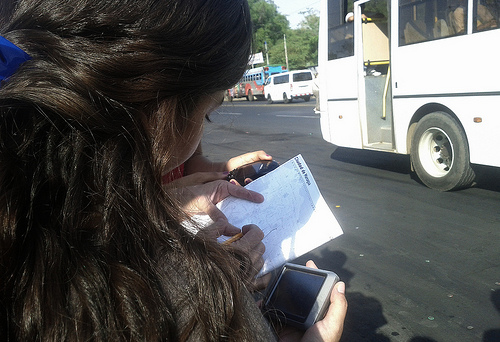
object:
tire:
[410, 111, 477, 192]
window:
[327, 0, 353, 62]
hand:
[197, 224, 266, 279]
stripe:
[327, 90, 500, 101]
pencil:
[220, 233, 243, 246]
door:
[356, 0, 394, 152]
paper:
[178, 153, 344, 277]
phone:
[226, 160, 277, 187]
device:
[260, 262, 340, 342]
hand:
[164, 180, 264, 222]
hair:
[0, 0, 247, 339]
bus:
[319, 0, 500, 192]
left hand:
[226, 150, 272, 186]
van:
[263, 70, 316, 103]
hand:
[268, 259, 348, 341]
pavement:
[200, 100, 500, 342]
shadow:
[321, 248, 385, 342]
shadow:
[330, 147, 500, 191]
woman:
[0, 0, 346, 342]